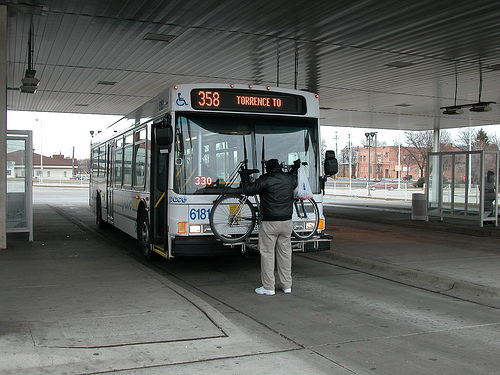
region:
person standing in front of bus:
[246, 149, 308, 314]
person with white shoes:
[244, 154, 308, 308]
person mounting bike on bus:
[204, 161, 328, 306]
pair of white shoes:
[246, 276, 301, 303]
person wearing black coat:
[234, 152, 312, 305]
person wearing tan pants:
[232, 145, 324, 317]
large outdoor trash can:
[405, 186, 431, 232]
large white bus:
[67, 77, 354, 273]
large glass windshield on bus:
[162, 113, 332, 200]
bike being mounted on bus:
[204, 167, 323, 248]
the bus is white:
[81, 77, 331, 272]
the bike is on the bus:
[211, 162, 321, 249]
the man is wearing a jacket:
[239, 169, 304, 219]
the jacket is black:
[233, 165, 305, 223]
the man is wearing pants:
[255, 212, 299, 302]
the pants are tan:
[255, 219, 297, 293]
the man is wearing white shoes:
[253, 283, 293, 300]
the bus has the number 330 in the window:
[192, 172, 214, 192]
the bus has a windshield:
[168, 110, 323, 209]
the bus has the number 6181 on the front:
[188, 206, 215, 225]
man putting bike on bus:
[249, 147, 295, 298]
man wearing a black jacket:
[257, 147, 305, 222]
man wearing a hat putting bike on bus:
[237, 154, 306, 299]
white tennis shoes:
[254, 282, 296, 300]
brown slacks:
[253, 216, 301, 286]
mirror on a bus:
[320, 139, 344, 191]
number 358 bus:
[167, 75, 324, 120]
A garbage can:
[409, 190, 433, 229]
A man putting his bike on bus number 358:
[84, 79, 325, 296]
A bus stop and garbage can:
[405, 145, 498, 234]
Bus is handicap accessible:
[164, 77, 191, 116]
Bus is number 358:
[189, 80, 230, 125]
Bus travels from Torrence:
[236, 88, 301, 112]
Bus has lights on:
[185, 212, 210, 235]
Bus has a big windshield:
[164, 96, 337, 205]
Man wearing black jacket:
[236, 154, 330, 225]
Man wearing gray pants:
[247, 212, 312, 291]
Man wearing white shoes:
[243, 274, 315, 307]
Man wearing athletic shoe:
[237, 277, 304, 299]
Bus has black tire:
[131, 192, 161, 266]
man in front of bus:
[88, 85, 388, 309]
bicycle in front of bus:
[197, 64, 404, 298]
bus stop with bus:
[9, 63, 249, 294]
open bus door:
[89, 96, 301, 288]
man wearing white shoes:
[224, 131, 363, 305]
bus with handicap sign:
[165, 76, 364, 293]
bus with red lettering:
[160, 66, 326, 227]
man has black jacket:
[200, 161, 356, 298]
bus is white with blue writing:
[92, 89, 357, 288]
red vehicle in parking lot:
[350, 156, 432, 243]